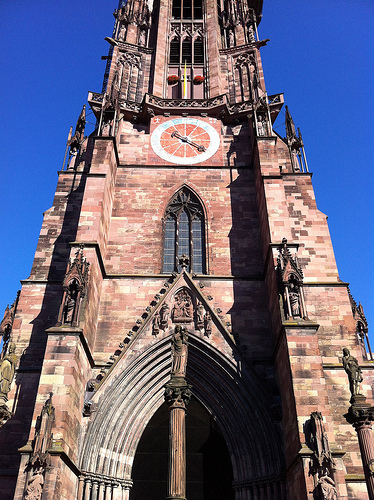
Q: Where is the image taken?
A: Close to tower.